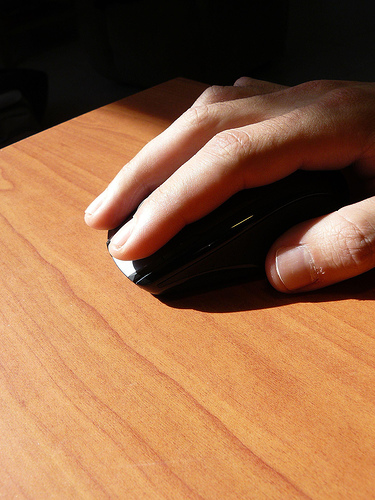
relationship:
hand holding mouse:
[82, 66, 365, 304] [104, 172, 360, 297]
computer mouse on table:
[104, 170, 341, 296] [72, 324, 280, 457]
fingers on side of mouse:
[265, 195, 375, 297] [159, 240, 240, 292]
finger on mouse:
[84, 79, 327, 229] [96, 152, 371, 291]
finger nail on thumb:
[276, 244, 317, 289] [265, 193, 373, 293]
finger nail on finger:
[78, 196, 109, 216] [73, 89, 262, 220]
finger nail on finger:
[110, 216, 148, 254] [106, 125, 307, 287]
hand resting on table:
[82, 66, 365, 304] [1, 68, 373, 499]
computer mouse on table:
[104, 170, 341, 296] [87, 75, 373, 302]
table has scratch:
[18, 310, 345, 472] [116, 454, 195, 473]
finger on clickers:
[100, 116, 299, 258] [99, 217, 178, 275]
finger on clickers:
[80, 91, 275, 231] [99, 217, 178, 275]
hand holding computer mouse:
[82, 77, 374, 295] [186, 214, 262, 278]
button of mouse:
[106, 215, 211, 277] [107, 146, 352, 317]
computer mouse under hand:
[104, 170, 341, 296] [82, 66, 365, 304]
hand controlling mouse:
[82, 66, 365, 304] [104, 172, 360, 297]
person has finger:
[82, 68, 373, 308] [232, 75, 288, 92]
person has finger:
[82, 68, 373, 308] [188, 83, 276, 106]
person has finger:
[82, 68, 373, 308] [96, 98, 288, 224]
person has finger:
[82, 68, 373, 308] [107, 117, 332, 261]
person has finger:
[82, 68, 373, 308] [265, 193, 372, 293]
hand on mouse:
[82, 66, 365, 304] [88, 146, 318, 305]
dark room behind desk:
[2, 4, 367, 143] [0, 61, 362, 480]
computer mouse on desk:
[104, 170, 341, 296] [0, 299, 374, 497]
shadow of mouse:
[161, 281, 374, 306] [82, 157, 317, 297]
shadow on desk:
[161, 281, 374, 306] [0, 61, 362, 480]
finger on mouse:
[107, 86, 345, 263] [105, 148, 317, 299]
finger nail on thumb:
[276, 244, 317, 289] [255, 189, 363, 309]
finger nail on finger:
[110, 216, 136, 247] [106, 102, 334, 263]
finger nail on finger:
[84, 196, 103, 214] [82, 92, 260, 230]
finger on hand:
[231, 76, 293, 92] [75, 51, 363, 294]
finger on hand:
[190, 76, 280, 113] [75, 51, 363, 294]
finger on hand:
[84, 79, 327, 229] [75, 51, 363, 294]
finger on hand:
[107, 86, 345, 263] [75, 51, 363, 294]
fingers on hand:
[260, 191, 374, 296] [75, 51, 363, 294]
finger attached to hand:
[107, 86, 345, 263] [94, 57, 373, 282]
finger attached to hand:
[84, 79, 327, 229] [94, 57, 373, 282]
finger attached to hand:
[181, 76, 263, 116] [94, 57, 373, 282]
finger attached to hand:
[231, 71, 291, 99] [94, 57, 373, 282]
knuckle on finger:
[181, 113, 279, 189] [111, 96, 351, 265]